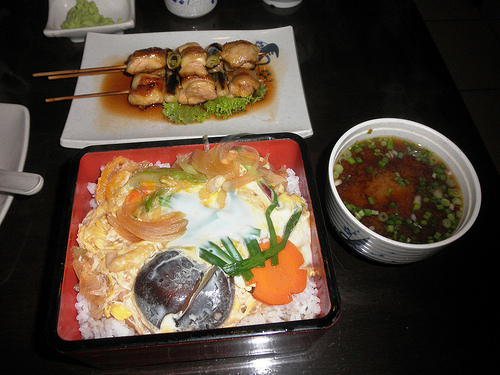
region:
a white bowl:
[312, 111, 489, 268]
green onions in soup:
[342, 133, 469, 250]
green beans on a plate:
[205, 211, 301, 291]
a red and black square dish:
[42, 130, 349, 351]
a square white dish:
[44, 23, 324, 146]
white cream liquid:
[175, 193, 261, 238]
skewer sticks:
[22, 55, 144, 115]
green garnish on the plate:
[165, 78, 272, 128]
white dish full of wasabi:
[37, 0, 139, 42]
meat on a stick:
[25, 30, 290, 126]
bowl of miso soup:
[315, 111, 490, 273]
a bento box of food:
[66, 150, 368, 336]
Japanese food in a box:
[71, 149, 343, 356]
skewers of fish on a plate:
[71, 35, 321, 121]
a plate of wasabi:
[36, 0, 126, 30]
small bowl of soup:
[312, 102, 479, 287]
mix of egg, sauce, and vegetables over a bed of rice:
[80, 161, 330, 353]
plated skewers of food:
[31, 33, 306, 114]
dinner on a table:
[42, 3, 491, 367]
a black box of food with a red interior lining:
[46, 124, 351, 356]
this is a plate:
[276, 91, 300, 125]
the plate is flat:
[281, 90, 303, 130]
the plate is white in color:
[281, 92, 301, 126]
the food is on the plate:
[86, 153, 283, 323]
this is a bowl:
[328, 115, 460, 261]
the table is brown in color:
[378, 287, 452, 367]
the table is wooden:
[351, 275, 469, 371]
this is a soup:
[361, 162, 411, 211]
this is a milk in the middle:
[193, 208, 233, 234]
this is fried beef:
[136, 42, 251, 95]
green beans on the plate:
[186, 202, 290, 287]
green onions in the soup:
[330, 123, 474, 248]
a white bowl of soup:
[320, 103, 484, 262]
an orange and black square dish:
[50, 128, 338, 363]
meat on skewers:
[32, 33, 280, 124]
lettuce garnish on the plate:
[153, 81, 285, 136]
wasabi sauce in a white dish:
[41, 0, 139, 32]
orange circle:
[236, 233, 308, 310]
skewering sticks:
[33, 60, 134, 108]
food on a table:
[25, 15, 488, 355]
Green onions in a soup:
[373, 207, 417, 239]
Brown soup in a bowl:
[329, 129, 464, 240]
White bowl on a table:
[324, 122, 481, 265]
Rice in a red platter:
[76, 292, 129, 337]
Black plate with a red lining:
[46, 147, 338, 363]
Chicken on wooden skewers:
[122, 41, 269, 102]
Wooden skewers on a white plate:
[29, 63, 135, 108]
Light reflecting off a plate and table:
[243, 329, 271, 372]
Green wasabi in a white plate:
[46, 1, 135, 36]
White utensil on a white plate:
[0, 163, 50, 205]